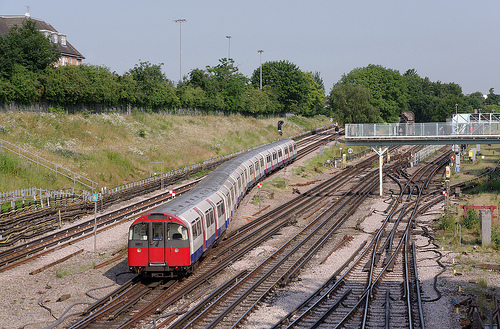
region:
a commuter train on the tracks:
[117, 125, 295, 285]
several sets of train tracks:
[240, 153, 429, 320]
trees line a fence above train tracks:
[3, 5, 313, 120]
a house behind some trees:
[2, 0, 131, 121]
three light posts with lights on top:
[166, 6, 289, 118]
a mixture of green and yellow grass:
[29, 114, 211, 187]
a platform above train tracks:
[334, 109, 493, 201]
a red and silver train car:
[112, 206, 219, 293]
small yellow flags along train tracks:
[422, 207, 482, 324]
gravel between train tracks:
[281, 190, 364, 322]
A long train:
[127, 136, 294, 285]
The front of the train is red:
[131, 216, 191, 269]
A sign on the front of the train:
[146, 212, 171, 220]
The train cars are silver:
[130, 138, 294, 276]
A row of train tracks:
[8, 111, 438, 323]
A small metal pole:
[90, 191, 100, 259]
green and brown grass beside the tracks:
[5, 110, 325, 210]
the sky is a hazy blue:
[4, 1, 499, 97]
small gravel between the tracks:
[249, 193, 391, 323]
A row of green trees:
[2, 38, 499, 132]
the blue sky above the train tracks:
[3, 2, 494, 92]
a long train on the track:
[123, 135, 298, 283]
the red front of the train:
[124, 212, 191, 272]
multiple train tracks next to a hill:
[67, 137, 455, 327]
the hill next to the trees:
[3, 103, 325, 218]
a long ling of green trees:
[0, 23, 496, 122]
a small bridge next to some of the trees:
[344, 120, 499, 172]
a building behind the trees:
[3, 15, 85, 67]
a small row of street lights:
[173, 12, 268, 87]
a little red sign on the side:
[442, 188, 450, 198]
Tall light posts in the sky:
[160, 7, 281, 92]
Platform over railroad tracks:
[337, 105, 492, 175]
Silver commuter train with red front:
[125, 130, 300, 285]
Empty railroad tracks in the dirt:
[275, 190, 442, 320]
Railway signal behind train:
[264, 107, 306, 176]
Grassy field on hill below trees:
[91, 63, 218, 152]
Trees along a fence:
[0, 32, 322, 117]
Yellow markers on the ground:
[435, 230, 466, 321]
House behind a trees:
[0, 15, 95, 110]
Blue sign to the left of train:
[78, 180, 226, 285]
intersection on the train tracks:
[352, 165, 443, 279]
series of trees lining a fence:
[2, 25, 327, 130]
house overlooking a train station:
[0, 2, 91, 89]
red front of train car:
[119, 205, 199, 290]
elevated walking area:
[335, 120, 492, 162]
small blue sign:
[90, 186, 101, 254]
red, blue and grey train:
[125, 132, 300, 294]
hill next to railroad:
[2, 94, 337, 181]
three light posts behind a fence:
[169, 13, 269, 110]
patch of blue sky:
[259, 3, 492, 53]